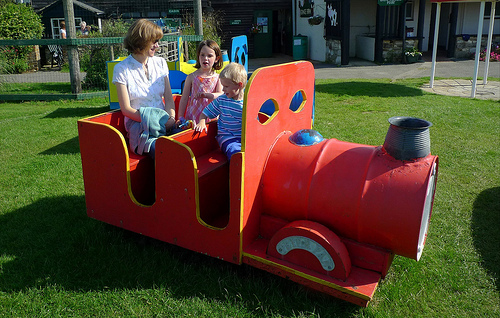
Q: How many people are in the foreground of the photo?
A: Three.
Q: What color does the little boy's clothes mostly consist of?
A: Blue.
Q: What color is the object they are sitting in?
A: Red.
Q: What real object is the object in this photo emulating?
A: A train.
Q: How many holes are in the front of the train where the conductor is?
A: Two.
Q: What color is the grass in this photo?
A: Green.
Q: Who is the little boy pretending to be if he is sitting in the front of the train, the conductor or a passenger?
A: The conductor.